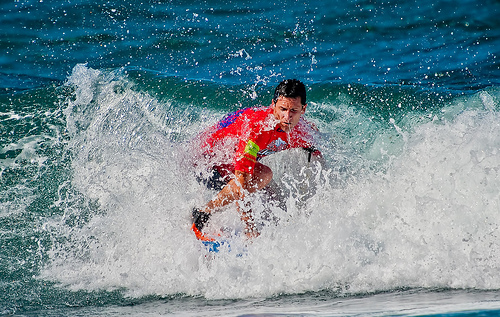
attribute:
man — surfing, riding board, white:
[184, 81, 350, 219]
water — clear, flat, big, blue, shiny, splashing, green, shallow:
[65, 125, 175, 285]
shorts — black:
[197, 171, 228, 190]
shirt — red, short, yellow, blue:
[208, 99, 277, 150]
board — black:
[201, 240, 285, 263]